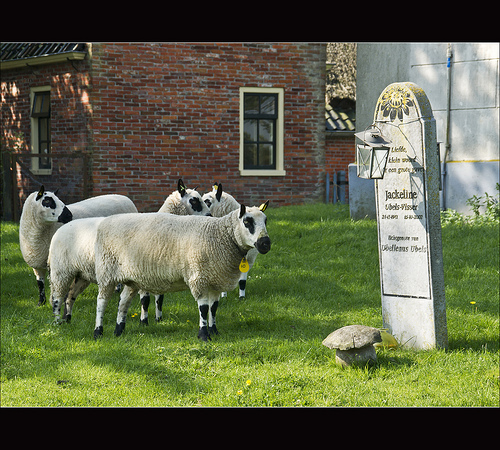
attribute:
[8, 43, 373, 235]
building — background, Brick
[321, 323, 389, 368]
toadstool — Small 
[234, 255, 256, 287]
tag — Identification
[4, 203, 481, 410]
grassy — Large 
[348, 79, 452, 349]
headstone — Tall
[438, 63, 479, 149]
trees — Shadows 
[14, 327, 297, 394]
area — grassy 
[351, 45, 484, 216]
cement — Large 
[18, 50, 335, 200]
brick — black 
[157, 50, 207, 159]
wall — side 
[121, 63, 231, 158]
bricks — red, section 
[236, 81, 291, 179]
frame — white 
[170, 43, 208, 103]
building — side 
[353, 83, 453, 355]
stone — tall gray grave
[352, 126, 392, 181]
lantern — small gray 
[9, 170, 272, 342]
sheep — white  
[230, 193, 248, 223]
ears — black 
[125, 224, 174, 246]
wool — white 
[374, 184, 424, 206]
letter — black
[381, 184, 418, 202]
letter — black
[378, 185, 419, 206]
letter — black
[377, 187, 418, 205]
letters — black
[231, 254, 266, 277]
tag — yellow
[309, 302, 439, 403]
mushroom — giant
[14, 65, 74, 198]
window — ajar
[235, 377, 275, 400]
flower — yellow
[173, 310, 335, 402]
grass — bright, green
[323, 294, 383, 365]
mushroom — giant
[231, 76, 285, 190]
window — large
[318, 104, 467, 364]
stone — large, grey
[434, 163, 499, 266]
bushes — small